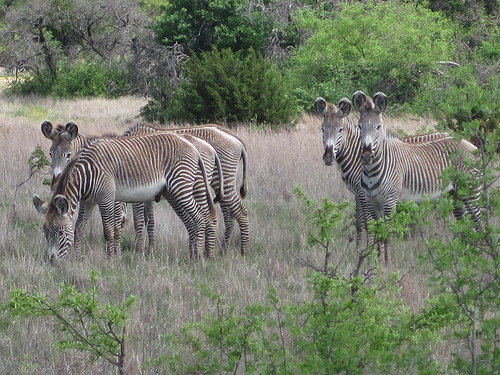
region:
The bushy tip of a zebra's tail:
[240, 178, 247, 200]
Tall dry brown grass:
[266, 160, 293, 179]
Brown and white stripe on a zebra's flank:
[176, 172, 191, 197]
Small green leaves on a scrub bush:
[336, 311, 359, 341]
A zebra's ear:
[51, 197, 72, 216]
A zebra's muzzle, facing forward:
[319, 103, 341, 165]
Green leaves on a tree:
[178, 8, 217, 29]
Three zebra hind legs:
[184, 218, 216, 260]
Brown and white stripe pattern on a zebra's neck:
[363, 163, 378, 191]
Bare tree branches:
[114, 16, 134, 37]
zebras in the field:
[36, 99, 255, 252]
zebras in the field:
[293, 89, 481, 275]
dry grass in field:
[183, 267, 219, 301]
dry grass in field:
[129, 277, 153, 318]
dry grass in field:
[286, 248, 317, 283]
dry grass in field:
[271, 208, 301, 246]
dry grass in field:
[36, 321, 63, 358]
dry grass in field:
[285, 153, 316, 189]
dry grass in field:
[249, 160, 285, 200]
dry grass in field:
[392, 236, 432, 287]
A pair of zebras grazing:
[37, 118, 252, 262]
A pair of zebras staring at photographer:
[310, 89, 493, 270]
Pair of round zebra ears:
[351, 89, 388, 115]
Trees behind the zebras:
[0, 0, 496, 125]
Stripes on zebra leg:
[93, 185, 114, 267]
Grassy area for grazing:
[1, 93, 498, 373]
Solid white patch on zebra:
[117, 179, 162, 203]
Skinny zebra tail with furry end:
[238, 147, 249, 198]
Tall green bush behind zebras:
[132, 42, 299, 128]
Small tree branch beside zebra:
[9, 144, 51, 222]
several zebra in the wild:
[13, 76, 493, 270]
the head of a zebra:
[27, 192, 82, 274]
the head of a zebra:
[40, 115, 80, 188]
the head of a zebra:
[309, 93, 351, 170]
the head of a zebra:
[349, 89, 391, 161]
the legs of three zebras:
[80, 201, 255, 263]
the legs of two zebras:
[345, 198, 497, 270]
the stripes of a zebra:
[95, 140, 185, 185]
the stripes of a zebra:
[381, 144, 441, 187]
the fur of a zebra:
[94, 145, 182, 187]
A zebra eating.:
[32, 130, 218, 281]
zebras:
[23, 63, 497, 260]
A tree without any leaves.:
[7, 6, 188, 97]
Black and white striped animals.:
[23, 90, 495, 254]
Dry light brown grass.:
[1, 78, 498, 374]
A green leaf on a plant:
[334, 25, 340, 28]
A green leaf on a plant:
[352, 20, 358, 25]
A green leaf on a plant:
[364, 53, 375, 56]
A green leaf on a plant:
[237, 57, 239, 59]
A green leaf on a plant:
[243, 67, 248, 75]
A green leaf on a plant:
[271, 84, 278, 88]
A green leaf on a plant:
[200, 74, 206, 78]